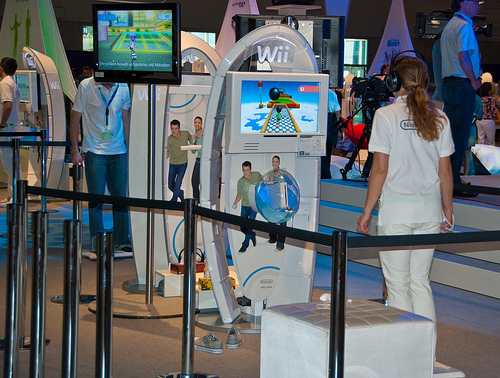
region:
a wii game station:
[233, 40, 343, 140]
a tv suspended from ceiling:
[75, 9, 210, 91]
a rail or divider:
[20, 175, 498, 283]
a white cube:
[255, 285, 452, 376]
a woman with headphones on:
[367, 47, 453, 327]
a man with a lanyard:
[87, 20, 132, 265]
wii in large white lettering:
[251, 28, 308, 77]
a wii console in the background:
[17, 45, 75, 212]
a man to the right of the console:
[432, 8, 499, 175]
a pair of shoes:
[185, 318, 255, 363]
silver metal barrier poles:
[30, 214, 114, 376]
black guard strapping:
[185, 202, 347, 249]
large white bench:
[235, 290, 440, 373]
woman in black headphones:
[366, 45, 436, 90]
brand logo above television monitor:
[241, 35, 302, 65]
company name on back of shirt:
[397, 115, 440, 136]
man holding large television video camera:
[413, 9, 496, 41]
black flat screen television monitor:
[81, 6, 184, 82]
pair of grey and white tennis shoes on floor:
[184, 320, 255, 354]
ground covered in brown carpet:
[120, 330, 180, 370]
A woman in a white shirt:
[356, 46, 451, 323]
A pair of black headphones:
[386, 44, 435, 88]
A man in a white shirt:
[68, 65, 131, 246]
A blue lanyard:
[92, 79, 126, 124]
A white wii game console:
[263, 178, 288, 207]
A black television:
[95, 6, 182, 83]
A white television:
[224, 70, 326, 154]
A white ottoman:
[258, 298, 433, 377]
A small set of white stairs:
[317, 182, 499, 296]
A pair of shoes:
[193, 323, 245, 355]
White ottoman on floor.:
[251, 295, 434, 375]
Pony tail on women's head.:
[375, 41, 450, 146]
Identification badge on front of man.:
[80, 55, 120, 150]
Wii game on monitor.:
[225, 70, 320, 150]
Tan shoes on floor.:
[190, 320, 245, 365]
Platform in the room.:
[450, 166, 496, 293]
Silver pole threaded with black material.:
[171, 186, 211, 372]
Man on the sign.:
[160, 111, 187, 206]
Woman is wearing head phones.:
[375, 45, 445, 150]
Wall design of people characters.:
[5, 5, 35, 55]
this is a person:
[360, 45, 461, 376]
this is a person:
[432, 0, 490, 200]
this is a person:
[60, 52, 132, 262]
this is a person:
[2, 56, 38, 217]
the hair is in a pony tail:
[392, 53, 437, 139]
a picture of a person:
[255, 145, 301, 257]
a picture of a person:
[225, 145, 261, 256]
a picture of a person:
[163, 105, 190, 217]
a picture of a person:
[185, 108, 226, 216]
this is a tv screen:
[89, 1, 178, 91]